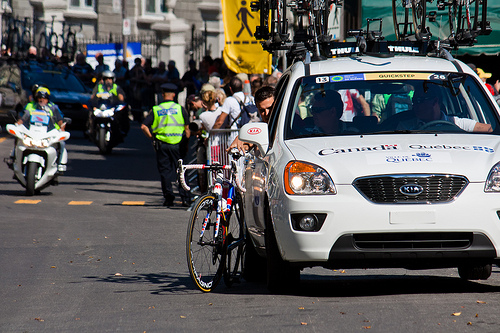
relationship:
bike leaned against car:
[179, 157, 244, 291] [235, 53, 497, 282]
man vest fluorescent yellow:
[142, 83, 189, 205] [150, 101, 188, 143]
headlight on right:
[485, 160, 499, 195] [238, 4, 499, 331]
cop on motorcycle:
[86, 73, 130, 137] [84, 93, 129, 156]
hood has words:
[284, 133, 499, 181] [322, 144, 495, 164]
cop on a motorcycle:
[86, 73, 130, 137] [6, 112, 71, 197]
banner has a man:
[221, 1, 270, 75] [236, 1, 254, 39]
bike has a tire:
[179, 157, 244, 291] [187, 194, 226, 293]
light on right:
[486, 161, 500, 191] [238, 4, 499, 331]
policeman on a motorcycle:
[91, 70, 126, 110] [84, 93, 129, 156]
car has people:
[235, 53, 497, 282] [304, 92, 494, 134]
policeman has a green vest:
[91, 70, 126, 110] [98, 82, 117, 95]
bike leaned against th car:
[179, 157, 244, 291] [235, 53, 497, 282]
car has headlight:
[235, 53, 497, 282] [485, 160, 499, 195]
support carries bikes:
[263, 40, 462, 63] [251, 1, 489, 42]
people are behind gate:
[187, 78, 269, 201] [202, 129, 239, 198]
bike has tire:
[179, 157, 244, 291] [187, 194, 226, 293]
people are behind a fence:
[187, 78, 269, 201] [205, 127, 249, 188]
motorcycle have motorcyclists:
[6, 112, 71, 197] [18, 88, 66, 135]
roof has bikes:
[250, 2, 489, 47] [253, 2, 492, 46]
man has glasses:
[305, 91, 358, 136] [311, 105, 336, 113]